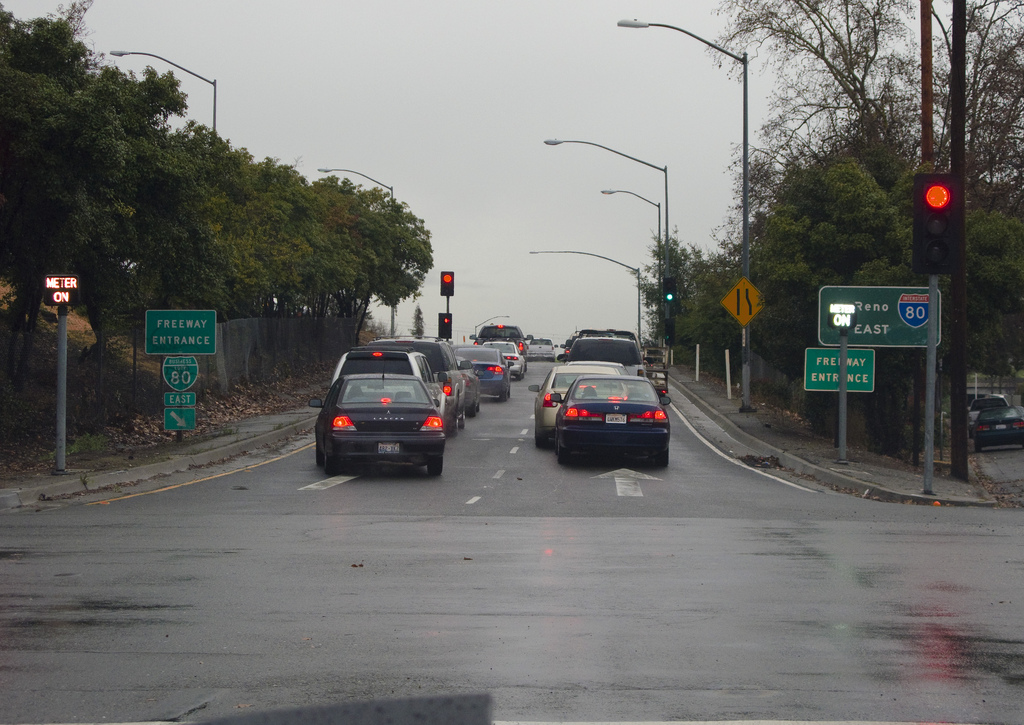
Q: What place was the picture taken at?
A: It was taken at the street.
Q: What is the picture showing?
A: It is showing a street.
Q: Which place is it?
A: It is a street.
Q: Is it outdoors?
A: Yes, it is outdoors.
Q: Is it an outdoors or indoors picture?
A: It is outdoors.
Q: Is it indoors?
A: No, it is outdoors.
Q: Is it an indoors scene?
A: No, it is outdoors.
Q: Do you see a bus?
A: No, there are no buses.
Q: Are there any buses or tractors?
A: No, there are no buses or tractors.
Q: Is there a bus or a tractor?
A: No, there are no buses or tractors.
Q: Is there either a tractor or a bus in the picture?
A: No, there are no buses or tractors.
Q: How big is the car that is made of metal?
A: The car is small.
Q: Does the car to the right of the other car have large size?
A: No, the car is small.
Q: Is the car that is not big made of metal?
A: Yes, the car is made of metal.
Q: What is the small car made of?
A: The car is made of metal.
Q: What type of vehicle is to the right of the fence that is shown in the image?
A: The vehicle is a car.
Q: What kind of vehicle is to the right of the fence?
A: The vehicle is a car.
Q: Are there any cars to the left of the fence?
A: No, the car is to the right of the fence.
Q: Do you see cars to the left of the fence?
A: No, the car is to the right of the fence.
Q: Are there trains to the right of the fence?
A: No, there is a car to the right of the fence.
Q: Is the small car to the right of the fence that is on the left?
A: Yes, the car is to the right of the fence.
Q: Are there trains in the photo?
A: No, there are no trains.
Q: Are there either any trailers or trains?
A: No, there are no trains or trailers.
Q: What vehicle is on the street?
A: The vehicle is a car.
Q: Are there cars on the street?
A: Yes, there is a car on the street.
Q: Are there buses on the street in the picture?
A: No, there is a car on the street.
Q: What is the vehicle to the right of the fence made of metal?
A: The vehicle is a car.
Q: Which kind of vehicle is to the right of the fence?
A: The vehicle is a car.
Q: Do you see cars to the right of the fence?
A: Yes, there is a car to the right of the fence.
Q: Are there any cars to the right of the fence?
A: Yes, there is a car to the right of the fence.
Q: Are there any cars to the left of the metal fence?
A: No, the car is to the right of the fence.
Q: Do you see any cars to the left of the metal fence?
A: No, the car is to the right of the fence.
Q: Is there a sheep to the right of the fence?
A: No, there is a car to the right of the fence.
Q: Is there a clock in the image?
A: No, there are no clocks.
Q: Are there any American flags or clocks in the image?
A: No, there are no clocks or American flags.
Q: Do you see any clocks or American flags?
A: No, there are no clocks or American flags.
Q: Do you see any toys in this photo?
A: No, there are no toys.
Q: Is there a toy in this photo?
A: No, there are no toys.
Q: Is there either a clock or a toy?
A: No, there are no toys or clocks.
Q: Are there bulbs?
A: No, there are no bulbs.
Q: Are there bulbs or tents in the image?
A: No, there are no bulbs or tents.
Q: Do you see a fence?
A: Yes, there is a fence.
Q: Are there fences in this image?
A: Yes, there is a fence.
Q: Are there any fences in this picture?
A: Yes, there is a fence.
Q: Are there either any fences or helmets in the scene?
A: Yes, there is a fence.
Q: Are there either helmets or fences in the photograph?
A: Yes, there is a fence.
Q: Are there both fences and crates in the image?
A: No, there is a fence but no crates.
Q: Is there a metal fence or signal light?
A: Yes, there is a metal fence.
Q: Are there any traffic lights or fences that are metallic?
A: Yes, the fence is metallic.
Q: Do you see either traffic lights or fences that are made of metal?
A: Yes, the fence is made of metal.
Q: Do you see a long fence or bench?
A: Yes, there is a long fence.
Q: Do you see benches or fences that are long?
A: Yes, the fence is long.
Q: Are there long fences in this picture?
A: Yes, there is a long fence.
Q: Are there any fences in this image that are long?
A: Yes, there is a fence that is long.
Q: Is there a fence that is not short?
A: Yes, there is a long fence.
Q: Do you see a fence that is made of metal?
A: Yes, there is a fence that is made of metal.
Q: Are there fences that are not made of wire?
A: Yes, there is a fence that is made of metal.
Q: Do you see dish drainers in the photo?
A: No, there are no dish drainers.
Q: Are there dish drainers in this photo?
A: No, there are no dish drainers.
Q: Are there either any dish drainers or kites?
A: No, there are no dish drainers or kites.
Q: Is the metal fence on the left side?
A: Yes, the fence is on the left of the image.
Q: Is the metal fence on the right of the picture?
A: No, the fence is on the left of the image.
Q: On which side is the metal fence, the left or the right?
A: The fence is on the left of the image.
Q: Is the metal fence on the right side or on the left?
A: The fence is on the left of the image.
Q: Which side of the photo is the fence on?
A: The fence is on the left of the image.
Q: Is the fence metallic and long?
A: Yes, the fence is metallic and long.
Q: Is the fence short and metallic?
A: No, the fence is metallic but long.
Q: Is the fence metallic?
A: Yes, the fence is metallic.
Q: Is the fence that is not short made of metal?
A: Yes, the fence is made of metal.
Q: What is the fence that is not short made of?
A: The fence is made of metal.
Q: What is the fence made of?
A: The fence is made of metal.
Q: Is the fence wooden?
A: No, the fence is metallic.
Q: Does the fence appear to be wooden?
A: No, the fence is metallic.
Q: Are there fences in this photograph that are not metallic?
A: No, there is a fence but it is metallic.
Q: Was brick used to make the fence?
A: No, the fence is made of metal.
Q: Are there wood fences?
A: No, there is a fence but it is made of metal.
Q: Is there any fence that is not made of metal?
A: No, there is a fence but it is made of metal.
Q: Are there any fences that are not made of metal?
A: No, there is a fence but it is made of metal.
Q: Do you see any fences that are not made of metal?
A: No, there is a fence but it is made of metal.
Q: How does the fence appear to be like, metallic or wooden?
A: The fence is metallic.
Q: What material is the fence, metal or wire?
A: The fence is made of metal.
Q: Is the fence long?
A: Yes, the fence is long.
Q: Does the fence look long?
A: Yes, the fence is long.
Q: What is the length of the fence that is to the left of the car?
A: The fence is long.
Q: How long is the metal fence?
A: The fence is long.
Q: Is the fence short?
A: No, the fence is long.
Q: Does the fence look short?
A: No, the fence is long.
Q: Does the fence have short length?
A: No, the fence is long.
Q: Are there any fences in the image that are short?
A: No, there is a fence but it is long.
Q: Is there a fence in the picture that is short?
A: No, there is a fence but it is long.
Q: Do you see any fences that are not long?
A: No, there is a fence but it is long.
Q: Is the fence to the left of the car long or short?
A: The fence is long.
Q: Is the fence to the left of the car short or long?
A: The fence is long.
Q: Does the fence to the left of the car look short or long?
A: The fence is long.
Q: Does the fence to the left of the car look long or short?
A: The fence is long.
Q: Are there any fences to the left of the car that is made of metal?
A: Yes, there is a fence to the left of the car.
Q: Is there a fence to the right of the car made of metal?
A: No, the fence is to the left of the car.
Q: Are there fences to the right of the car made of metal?
A: No, the fence is to the left of the car.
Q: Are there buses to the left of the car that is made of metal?
A: No, there is a fence to the left of the car.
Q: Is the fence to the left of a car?
A: Yes, the fence is to the left of a car.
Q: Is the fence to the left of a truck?
A: No, the fence is to the left of a car.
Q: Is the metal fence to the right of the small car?
A: No, the fence is to the left of the car.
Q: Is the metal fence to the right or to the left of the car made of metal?
A: The fence is to the left of the car.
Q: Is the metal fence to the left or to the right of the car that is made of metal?
A: The fence is to the left of the car.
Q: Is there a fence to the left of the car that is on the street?
A: Yes, there is a fence to the left of the car.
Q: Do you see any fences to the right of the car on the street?
A: No, the fence is to the left of the car.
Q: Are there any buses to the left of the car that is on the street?
A: No, there is a fence to the left of the car.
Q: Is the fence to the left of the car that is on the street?
A: Yes, the fence is to the left of the car.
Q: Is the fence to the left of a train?
A: No, the fence is to the left of the car.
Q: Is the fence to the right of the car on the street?
A: No, the fence is to the left of the car.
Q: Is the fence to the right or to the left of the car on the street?
A: The fence is to the left of the car.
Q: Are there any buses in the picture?
A: No, there are no buses.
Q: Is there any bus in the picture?
A: No, there are no buses.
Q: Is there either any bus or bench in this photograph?
A: No, there are no buses or benches.